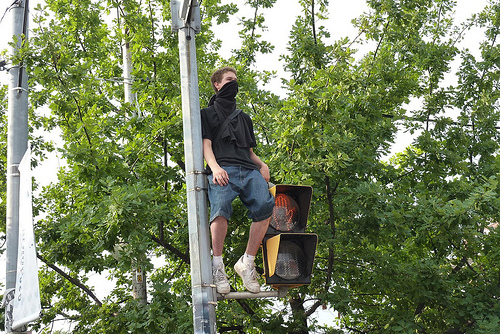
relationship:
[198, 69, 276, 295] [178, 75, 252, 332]
boy standing on pole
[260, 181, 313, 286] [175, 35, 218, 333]
holder to pole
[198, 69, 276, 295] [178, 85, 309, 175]
boy wearing shirt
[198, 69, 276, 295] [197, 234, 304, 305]
boy wearing socks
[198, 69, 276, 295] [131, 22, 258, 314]
boy on pole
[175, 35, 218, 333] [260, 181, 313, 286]
pole for holder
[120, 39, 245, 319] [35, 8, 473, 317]
pole next to trees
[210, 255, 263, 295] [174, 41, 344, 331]
shoes on man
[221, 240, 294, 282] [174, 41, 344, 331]
socks on man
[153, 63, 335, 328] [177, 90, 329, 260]
boy has shirt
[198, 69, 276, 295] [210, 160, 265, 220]
boy wearing shorts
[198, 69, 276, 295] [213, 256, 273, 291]
boy wearing shoes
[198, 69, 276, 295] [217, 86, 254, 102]
boy wearing mask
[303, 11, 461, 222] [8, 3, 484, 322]
section with trees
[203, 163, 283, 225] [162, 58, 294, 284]
shorts on man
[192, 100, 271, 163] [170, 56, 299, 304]
shirt on man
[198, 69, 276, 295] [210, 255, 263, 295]
boy wearing shoes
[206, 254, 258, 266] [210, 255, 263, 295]
socks inside shoes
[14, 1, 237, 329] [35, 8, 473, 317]
steel poles near trees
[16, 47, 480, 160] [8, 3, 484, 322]
wires going through trees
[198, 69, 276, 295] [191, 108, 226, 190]
boy sitting arm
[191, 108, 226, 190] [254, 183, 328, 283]
arm holds light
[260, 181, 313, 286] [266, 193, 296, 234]
holder indicates hand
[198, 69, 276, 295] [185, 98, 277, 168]
boy in shirt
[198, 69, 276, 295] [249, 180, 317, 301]
boy standing on light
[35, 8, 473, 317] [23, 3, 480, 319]
trees in background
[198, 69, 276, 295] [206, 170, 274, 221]
boy wearing shorts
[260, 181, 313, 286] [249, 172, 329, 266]
holder on holder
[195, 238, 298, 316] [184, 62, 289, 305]
shoes on boy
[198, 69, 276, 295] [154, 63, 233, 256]
boy on pole